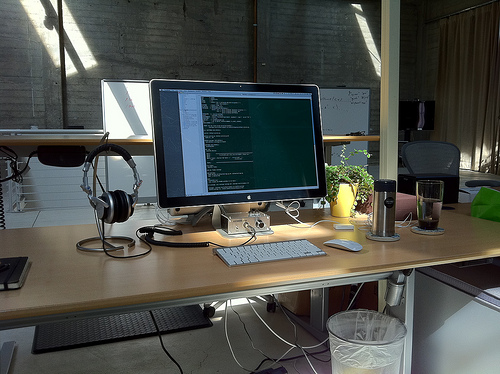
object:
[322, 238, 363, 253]
mouse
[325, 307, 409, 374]
basket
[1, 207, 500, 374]
desk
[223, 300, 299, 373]
cords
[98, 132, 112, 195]
stand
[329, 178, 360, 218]
pot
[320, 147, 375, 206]
plant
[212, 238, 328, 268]
keyboard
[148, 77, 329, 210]
monitor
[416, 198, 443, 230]
water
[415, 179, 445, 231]
glass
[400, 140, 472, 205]
chair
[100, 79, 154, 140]
whiteboard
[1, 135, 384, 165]
desk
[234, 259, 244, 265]
keys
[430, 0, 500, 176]
curtain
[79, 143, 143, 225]
headphones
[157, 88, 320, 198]
screen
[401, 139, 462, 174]
back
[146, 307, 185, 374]
cable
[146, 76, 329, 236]
computer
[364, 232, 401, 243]
coaster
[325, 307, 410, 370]
lining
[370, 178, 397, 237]
container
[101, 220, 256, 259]
wires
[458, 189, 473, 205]
seat